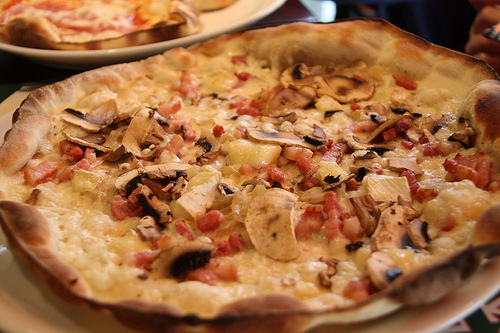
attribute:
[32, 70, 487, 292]
pizza — handmade, cooked, brown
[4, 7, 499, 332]
plate — white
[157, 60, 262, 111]
cheese — tan, white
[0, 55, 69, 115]
table — dark, wooden, colorful, black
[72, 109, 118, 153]
mushrooms — vegetable, chopped, brown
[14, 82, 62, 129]
bread — brown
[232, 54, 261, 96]
spices — small, red, yellow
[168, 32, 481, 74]
crust — crisp, burned, thin, crispy, brown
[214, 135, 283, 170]
pineapple — piece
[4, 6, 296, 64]
plate — white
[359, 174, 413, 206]
chicken — white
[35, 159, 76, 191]
topping — pink